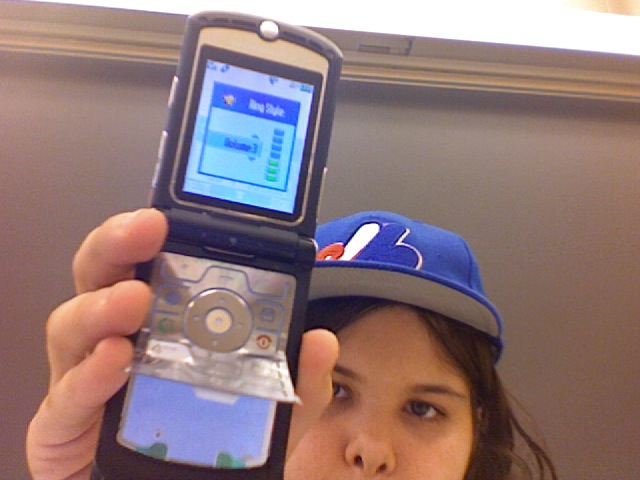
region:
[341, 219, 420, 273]
the logo on the hat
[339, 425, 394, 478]
the womens nose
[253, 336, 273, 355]
a red button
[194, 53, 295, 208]
screen of the cellphone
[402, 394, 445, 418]
the womens eye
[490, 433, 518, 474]
hair is brown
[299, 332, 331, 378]
a thumb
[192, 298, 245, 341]
the center button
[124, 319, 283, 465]
Broken keyboard on the phone.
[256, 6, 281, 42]
Small carrier emblem on the phone.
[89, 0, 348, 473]
Broken blue and white Motorola flip phone.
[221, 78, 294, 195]
Display of volume on the screen.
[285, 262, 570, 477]
Face of a girl underneath the hat.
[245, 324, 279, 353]
Red button symbolizing end call.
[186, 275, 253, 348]
Small arrows on the phone for the menu.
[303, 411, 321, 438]
The woman is holding a large orange.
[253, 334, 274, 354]
red button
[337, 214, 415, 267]
logo on the hat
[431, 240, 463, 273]
hat is blue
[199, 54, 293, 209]
the screen of the cellphone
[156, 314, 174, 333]
a button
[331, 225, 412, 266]
logo is red, white and blue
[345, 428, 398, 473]
a nose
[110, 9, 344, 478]
Mid 2000s flip phone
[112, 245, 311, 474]
Face of number pad peeling off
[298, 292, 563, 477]
Child has stringy brown hair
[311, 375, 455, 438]
Child has blue eyes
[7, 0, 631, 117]
White molding at top of the wall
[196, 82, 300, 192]
Screen indicates volume at 3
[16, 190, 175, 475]
three fingers on left side of phone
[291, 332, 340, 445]
Thumb on right side of phone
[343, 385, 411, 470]
Very smooth bridge of nose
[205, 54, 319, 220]
screen on cell phone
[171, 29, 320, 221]
the screen is on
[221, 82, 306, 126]
the banner is blue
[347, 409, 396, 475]
nose of a woman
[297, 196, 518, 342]
girl wearing ball cap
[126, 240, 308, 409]
cell phone keypad is broke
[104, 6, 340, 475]
woman holding flip phone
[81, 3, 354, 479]
woman holding cell phone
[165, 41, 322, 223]
screen on phone is on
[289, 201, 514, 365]
womans ball cap is blue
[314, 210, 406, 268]
team logo on cap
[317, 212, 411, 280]
logo on cap is red white and blue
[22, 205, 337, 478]
right hand holding cell phone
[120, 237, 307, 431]
keypad on phone is silver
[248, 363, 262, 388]
a button on the phone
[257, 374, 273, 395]
a button on the phone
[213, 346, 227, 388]
a button on the phone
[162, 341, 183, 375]
a button on the phone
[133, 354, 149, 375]
a button on the phone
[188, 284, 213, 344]
a button on the phone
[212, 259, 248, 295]
a button on the phone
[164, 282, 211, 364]
a button on the phone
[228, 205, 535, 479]
Woman in a blue hat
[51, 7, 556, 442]
Woman holding black phone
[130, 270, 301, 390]
Buttons on black phone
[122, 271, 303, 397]
Buttons on cell phone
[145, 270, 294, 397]
Silver buttons on black phone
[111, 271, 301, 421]
Silver buttons on black phone